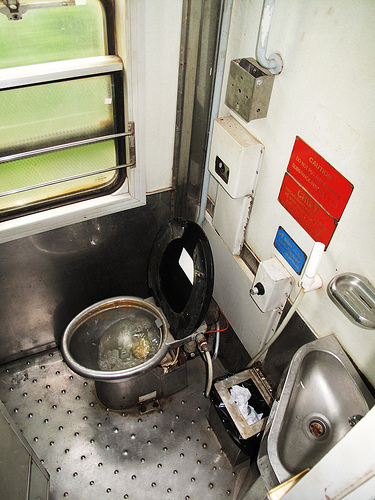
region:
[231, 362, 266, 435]
paper inside the waste basket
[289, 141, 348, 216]
caution sign on the wall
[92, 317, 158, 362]
water in the toilet bowl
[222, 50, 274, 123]
box on the wall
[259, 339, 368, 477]
metal sink in the corner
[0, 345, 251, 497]
silver colored metal floor with bubble grids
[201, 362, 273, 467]
trash receptacle filled with paper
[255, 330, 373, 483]
stainless steel corner sink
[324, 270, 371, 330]
empty metal soap holder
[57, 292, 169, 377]
rusted out toilet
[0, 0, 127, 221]
green tinted glass windows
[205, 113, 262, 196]
paper towel dispenser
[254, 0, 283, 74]
safety grab bar handle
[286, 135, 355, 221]
red sticker on the wall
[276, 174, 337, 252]
red sticker on the wall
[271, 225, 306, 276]
blue sticker on the wall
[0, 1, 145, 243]
window above the toilet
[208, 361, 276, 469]
garbage in the garbage can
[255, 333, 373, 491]
metal sink above trash can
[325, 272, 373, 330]
soap dish above the sink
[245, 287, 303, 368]
cord beside the trash can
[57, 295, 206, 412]
toilet is metal and silver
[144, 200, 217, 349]
Black lid of a toilet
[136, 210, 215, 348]
The toilet seat is open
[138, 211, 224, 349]
The black toilet seat is open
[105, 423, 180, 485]
The floor has bumps on it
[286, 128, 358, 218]
Sign on the wall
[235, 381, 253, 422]
White tissue paper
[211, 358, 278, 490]
Trashcan is full of trash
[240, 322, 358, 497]
Sink is in the corner of the wall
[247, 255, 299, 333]
Button flushes the contents of the toilet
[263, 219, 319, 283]
blue sign is mounted below the red sign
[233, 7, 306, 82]
Safety bar is mounted on the wall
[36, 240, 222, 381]
a dirty toilet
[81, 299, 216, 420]
a bathroom silver toilet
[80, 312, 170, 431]
a silver bathroom toilet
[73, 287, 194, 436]
a toilet is silver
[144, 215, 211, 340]
toilet seat is black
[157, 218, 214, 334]
toilet lid is black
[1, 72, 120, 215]
window next to toilet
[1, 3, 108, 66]
window next to toilet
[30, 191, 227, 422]
a filthy small toilet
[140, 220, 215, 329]
seat of the toilet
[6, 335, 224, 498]
rivets on the floor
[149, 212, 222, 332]
lid of the toilet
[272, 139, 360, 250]
red sign on the wall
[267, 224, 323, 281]
blue sign on the wall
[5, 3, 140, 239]
window in the room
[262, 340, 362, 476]
sink net to toilet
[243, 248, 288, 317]
white box on wall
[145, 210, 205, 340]
the seat of a toilet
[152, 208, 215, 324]
the lid of a toilet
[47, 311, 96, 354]
the rim of a toilet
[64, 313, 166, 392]
the bowl of a toilet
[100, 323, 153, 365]
the water of a toilet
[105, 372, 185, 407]
the base of a toilet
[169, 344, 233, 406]
the pipes of a toilet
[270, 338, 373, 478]
a sink that is grey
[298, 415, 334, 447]
the drain in a sink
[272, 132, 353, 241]
a sign that is red in color